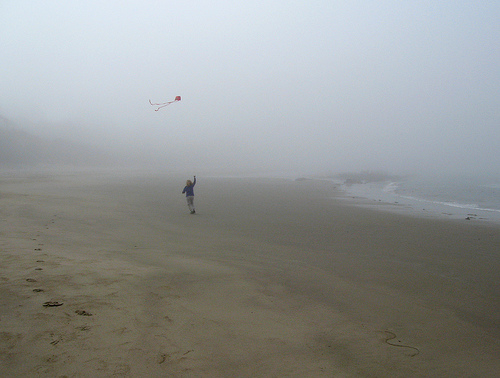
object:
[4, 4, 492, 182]
fog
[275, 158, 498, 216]
coast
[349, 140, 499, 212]
ocean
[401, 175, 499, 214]
water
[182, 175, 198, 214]
boy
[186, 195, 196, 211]
pants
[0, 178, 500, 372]
ground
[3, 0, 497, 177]
foggy sky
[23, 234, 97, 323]
marks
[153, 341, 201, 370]
marks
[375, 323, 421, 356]
marks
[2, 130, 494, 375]
sandy ground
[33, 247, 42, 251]
footstep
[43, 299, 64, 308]
footstep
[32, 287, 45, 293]
footstep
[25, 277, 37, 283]
footstep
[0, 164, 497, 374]
sand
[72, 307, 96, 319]
foot imprints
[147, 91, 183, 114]
kite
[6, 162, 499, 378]
beach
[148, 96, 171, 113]
tail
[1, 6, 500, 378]
air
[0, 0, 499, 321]
weather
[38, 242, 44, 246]
imprints